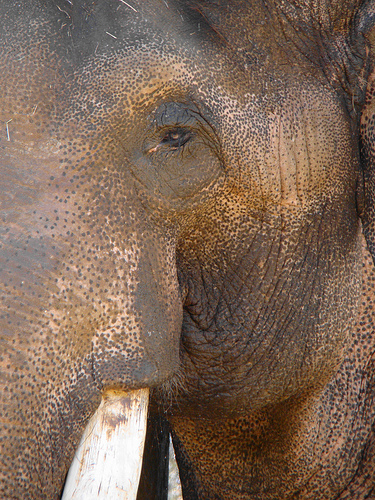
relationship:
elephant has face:
[1, 1, 375, 500] [3, 4, 342, 431]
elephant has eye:
[1, 1, 375, 500] [147, 122, 199, 150]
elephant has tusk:
[1, 1, 375, 500] [58, 385, 150, 500]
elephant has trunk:
[1, 1, 375, 500] [3, 382, 104, 499]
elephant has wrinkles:
[1, 1, 375, 500] [186, 112, 328, 403]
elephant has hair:
[1, 1, 375, 500] [150, 349, 191, 446]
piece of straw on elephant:
[104, 31, 119, 41] [1, 1, 375, 500]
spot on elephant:
[49, 175, 56, 181] [1, 1, 375, 500]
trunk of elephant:
[3, 382, 104, 499] [1, 1, 375, 500]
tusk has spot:
[58, 385, 150, 500] [100, 412, 128, 440]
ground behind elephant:
[166, 435, 185, 499] [1, 1, 375, 500]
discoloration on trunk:
[2, 235, 138, 473] [3, 382, 104, 499]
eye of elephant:
[147, 122, 199, 150] [1, 1, 375, 500]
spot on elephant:
[114, 250, 122, 257] [1, 1, 375, 500]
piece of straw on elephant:
[120, 1, 137, 13] [1, 1, 375, 500]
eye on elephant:
[147, 122, 199, 150] [1, 1, 375, 500]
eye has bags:
[147, 122, 199, 150] [129, 145, 224, 198]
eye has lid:
[147, 122, 199, 150] [147, 99, 210, 139]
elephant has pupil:
[1, 1, 375, 500] [171, 132, 177, 137]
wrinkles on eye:
[128, 98, 229, 206] [147, 122, 199, 150]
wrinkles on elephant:
[186, 112, 328, 403] [1, 1, 375, 500]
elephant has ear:
[1, 1, 375, 500] [338, 3, 375, 260]